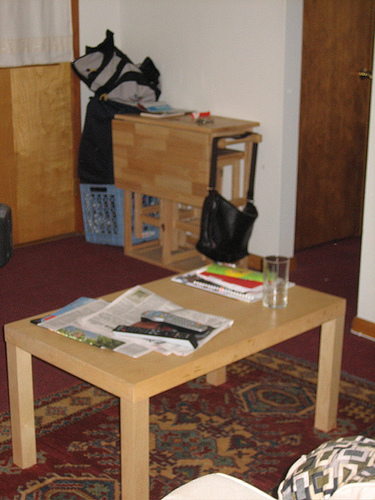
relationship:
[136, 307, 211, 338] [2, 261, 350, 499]
remote on table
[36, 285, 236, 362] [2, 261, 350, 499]
newspaper on table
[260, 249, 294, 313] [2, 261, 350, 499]
glass on table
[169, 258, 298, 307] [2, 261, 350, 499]
books on table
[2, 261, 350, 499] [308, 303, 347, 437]
table has leg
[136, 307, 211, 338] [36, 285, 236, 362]
remote on newspaper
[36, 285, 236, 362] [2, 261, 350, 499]
papers on table